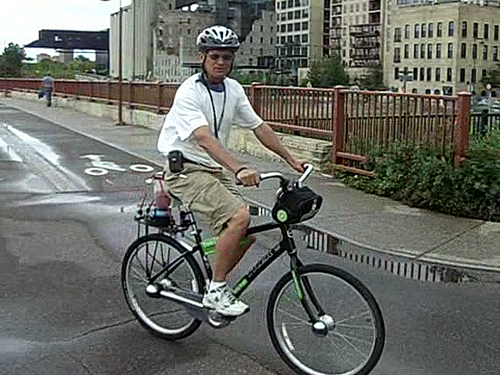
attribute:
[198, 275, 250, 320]
sneaker — white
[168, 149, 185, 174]
cell phone — black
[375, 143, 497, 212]
bushes — green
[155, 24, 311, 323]
man — riding 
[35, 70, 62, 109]
person — walking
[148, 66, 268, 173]
shirt — white